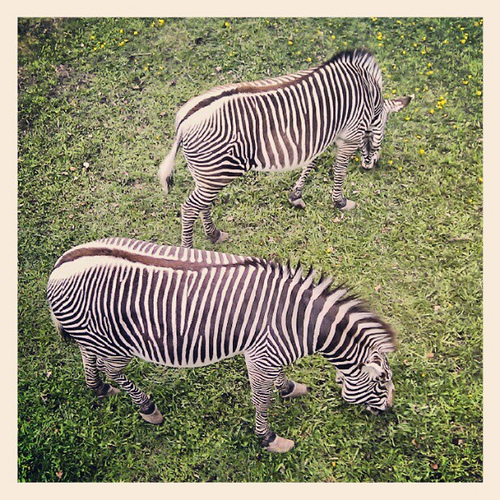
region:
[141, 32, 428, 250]
this is a zebra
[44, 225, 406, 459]
this is a zebra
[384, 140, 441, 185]
small yellow flowers on the field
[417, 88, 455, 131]
small yellow flowers on the field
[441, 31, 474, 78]
small yellow flowers on the field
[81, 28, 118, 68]
small yellow flowers on the field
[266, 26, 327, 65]
small yellow flowers on the field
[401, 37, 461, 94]
small yellow flowers on the field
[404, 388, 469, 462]
this is grass on the field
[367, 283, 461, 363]
this is grass on the field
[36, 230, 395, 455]
a zebra eating grass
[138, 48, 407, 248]
a zebra eating grass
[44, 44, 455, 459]
a pair of zebras eating grass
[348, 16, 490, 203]
yellow flowers in a field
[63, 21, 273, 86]
yellow flowers in a field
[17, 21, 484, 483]
a field of grass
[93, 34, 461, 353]
a field of light colored grass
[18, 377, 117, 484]
a patch of dark green grass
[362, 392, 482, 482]
a patch of dark green grass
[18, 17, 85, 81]
a patch of dark green grass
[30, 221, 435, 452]
a full grown adult zebra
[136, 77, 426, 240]
a small baby black and white zebra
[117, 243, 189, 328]
the striped pattern of a zebra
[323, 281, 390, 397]
the head of an adult zebra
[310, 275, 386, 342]
the mane of an adult zebra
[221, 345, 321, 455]
the front legs of an adult zebra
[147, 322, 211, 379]
the belly of an adult zebra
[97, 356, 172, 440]
the hind legs of an adult zebra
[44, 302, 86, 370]
the tail of an adult zebra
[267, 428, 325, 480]
the hooves of an adult zebra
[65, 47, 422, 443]
two zebras are grazing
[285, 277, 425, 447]
the head is down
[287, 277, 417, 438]
the zebra is eating grass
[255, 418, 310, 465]
the hooves are white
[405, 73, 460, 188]
flowers in the grass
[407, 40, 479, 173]
the flowers are yellow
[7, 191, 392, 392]
the zebra is black and white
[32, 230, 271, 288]
the stripe down the back is black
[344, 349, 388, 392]
the ear is white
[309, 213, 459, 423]
the grass is healthy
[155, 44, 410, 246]
A zebra eating grass.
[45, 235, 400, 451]
A black and white zebra.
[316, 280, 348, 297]
Part of the zebra's mane.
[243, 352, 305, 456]
The zebra's front legs.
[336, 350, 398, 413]
The head of the zebra.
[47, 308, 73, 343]
The zebra's tail.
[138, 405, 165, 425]
The zebra's hoof.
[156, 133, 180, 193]
The zebra's tail.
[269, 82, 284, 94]
Part of a stripe on the zebra's back.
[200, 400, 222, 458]
Part of the grass.